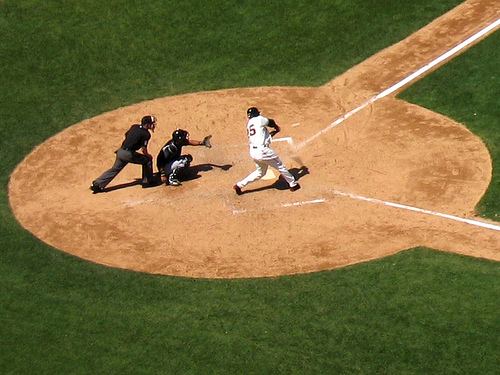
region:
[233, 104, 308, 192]
a batter swinging a bat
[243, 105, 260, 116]
a black helmet on a batter's head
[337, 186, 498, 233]
a white line on a baseball field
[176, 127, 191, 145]
a catcher's mask on a catcher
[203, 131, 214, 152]
a mitt on a catcher's hand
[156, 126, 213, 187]
a catcher squatted behind a batter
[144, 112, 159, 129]
a black mask on an umpire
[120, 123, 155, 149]
a black shirt on an umpire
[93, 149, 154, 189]
gray pants on an umpire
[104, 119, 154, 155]
the shirt is black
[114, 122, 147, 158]
the shirt is black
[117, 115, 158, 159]
the shirt is black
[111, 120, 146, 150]
the shirt is black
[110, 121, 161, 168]
the shirt is black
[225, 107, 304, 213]
the uniform is white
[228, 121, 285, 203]
the uniform is white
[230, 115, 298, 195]
the uniform is white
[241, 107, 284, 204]
the uniform is white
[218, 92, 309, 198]
THIS IS A BATTER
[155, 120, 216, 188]
THIS IS A CATCHER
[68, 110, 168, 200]
THE UMPIRE IS WEARING GREY PANTS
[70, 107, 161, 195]
THE UMPIRE IS WEARING A BLACK SHIRT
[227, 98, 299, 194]
THE BATTER IS WEARING A WHITE UNIFORM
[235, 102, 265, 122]
THE BATTER IS WEARING A BLACK HELMET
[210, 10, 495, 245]
THE WHITE LINES ARE PAINTED ON THE GROUND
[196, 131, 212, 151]
THE CATCHER IS WEARING A MITT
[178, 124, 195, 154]
THE CATCHER IS WEARING A MASK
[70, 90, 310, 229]
players in dirt circle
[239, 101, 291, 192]
man swinging base ball bat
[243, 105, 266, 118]
black batting helmet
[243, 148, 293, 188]
white baseball pants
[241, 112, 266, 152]
white jersey with number on it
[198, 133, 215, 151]
black catchers mitt in hand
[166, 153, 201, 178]
shin guards on knees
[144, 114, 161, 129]
umpire mask on man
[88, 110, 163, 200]
umpire squatting down behind catcher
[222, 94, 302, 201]
batter in batting box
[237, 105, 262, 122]
black helmet on batter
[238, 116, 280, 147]
white jersey on batter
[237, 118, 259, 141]
numbers on back of jersey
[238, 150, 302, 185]
white pants on bottom of jersey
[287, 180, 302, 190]
black cleats on player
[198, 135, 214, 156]
catchers glove in players hand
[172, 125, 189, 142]
black helmet on catcher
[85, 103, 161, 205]
umpire kneeling behind home plate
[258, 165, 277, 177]
a white base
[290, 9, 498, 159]
a long white line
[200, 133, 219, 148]
a baseball glove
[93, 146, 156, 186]
a man's gray pants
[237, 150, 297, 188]
a man's white uniform pants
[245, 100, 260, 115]
a black baseball helmet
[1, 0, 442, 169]
a section of green grass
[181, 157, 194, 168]
a black leg pad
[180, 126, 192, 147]
a black face mask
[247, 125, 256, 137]
a red number five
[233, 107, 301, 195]
the batter is swinging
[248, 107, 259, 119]
the helmet is black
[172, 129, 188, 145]
the helmet is black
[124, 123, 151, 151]
the shirt is black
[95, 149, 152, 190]
the pants are gray